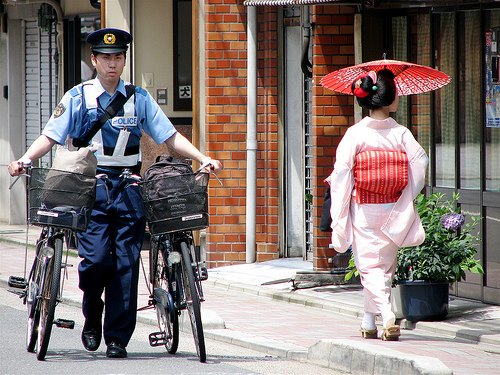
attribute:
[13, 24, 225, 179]
policeman — police officer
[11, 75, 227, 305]
uniform — blue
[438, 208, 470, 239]
flower — purple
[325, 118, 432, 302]
kimono — pink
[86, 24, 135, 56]
hat — black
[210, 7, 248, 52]
wall — red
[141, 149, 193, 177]
bag — black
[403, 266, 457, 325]
pot — big